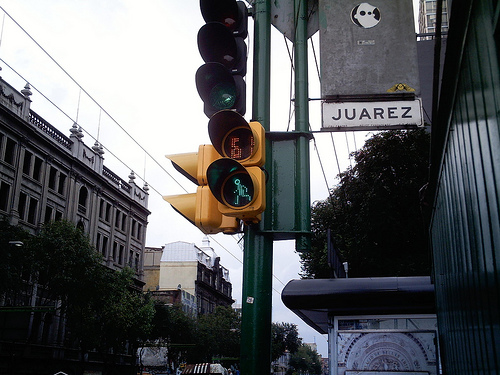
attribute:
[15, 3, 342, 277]
sky — gray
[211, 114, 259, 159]
light — red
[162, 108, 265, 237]
cover — yellow 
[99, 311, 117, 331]
leaf — green 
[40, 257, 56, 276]
leaf — green 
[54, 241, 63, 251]
leaf — green 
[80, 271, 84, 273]
leaf — green 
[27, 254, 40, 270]
leaf — green 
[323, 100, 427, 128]
sign — black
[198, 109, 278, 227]
light — peatonal, yellow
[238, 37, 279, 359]
pole — green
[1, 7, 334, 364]
sky — gray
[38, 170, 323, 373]
trees — tall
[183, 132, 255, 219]
light — peatonal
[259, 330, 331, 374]
man — green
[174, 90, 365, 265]
light — green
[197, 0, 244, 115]
lights — yellow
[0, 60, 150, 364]
building — made of brick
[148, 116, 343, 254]
lights — yellow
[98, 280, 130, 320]
leaves — green 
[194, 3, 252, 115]
traffic light — off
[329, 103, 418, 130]
writings — bold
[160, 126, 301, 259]
traffic light — peatonal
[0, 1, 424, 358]
sky — bright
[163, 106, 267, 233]
traffic light — peatonal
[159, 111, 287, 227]
traffic light — peatonal